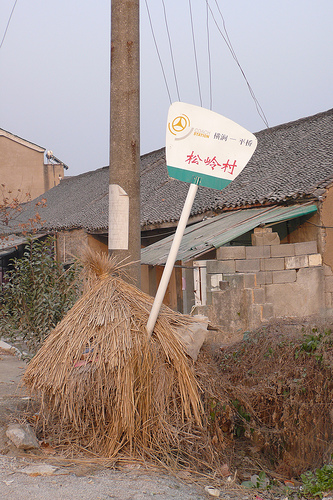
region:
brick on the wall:
[232, 257, 255, 271]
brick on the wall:
[270, 244, 294, 257]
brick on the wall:
[274, 272, 289, 282]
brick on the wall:
[246, 274, 257, 286]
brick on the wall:
[259, 305, 270, 317]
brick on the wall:
[243, 248, 264, 257]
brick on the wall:
[238, 273, 255, 284]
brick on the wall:
[250, 232, 272, 248]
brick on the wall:
[246, 247, 276, 259]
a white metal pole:
[142, 187, 200, 345]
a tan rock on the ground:
[2, 420, 37, 453]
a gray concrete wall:
[216, 227, 324, 279]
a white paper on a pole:
[107, 182, 133, 256]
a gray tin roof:
[44, 177, 90, 224]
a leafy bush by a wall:
[15, 229, 73, 341]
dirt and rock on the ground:
[6, 470, 260, 493]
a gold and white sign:
[163, 102, 257, 171]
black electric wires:
[143, 14, 240, 76]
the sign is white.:
[159, 95, 258, 195]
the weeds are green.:
[298, 460, 331, 497]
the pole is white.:
[140, 179, 204, 340]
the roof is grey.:
[0, 108, 331, 241]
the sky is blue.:
[0, 0, 331, 141]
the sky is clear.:
[0, 0, 330, 120]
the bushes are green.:
[3, 234, 86, 341]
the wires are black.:
[139, 0, 278, 138]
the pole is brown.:
[102, 1, 146, 280]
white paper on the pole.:
[99, 180, 131, 257]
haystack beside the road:
[29, 244, 206, 464]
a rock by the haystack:
[7, 421, 40, 447]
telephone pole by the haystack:
[110, 0, 141, 284]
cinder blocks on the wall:
[194, 226, 326, 347]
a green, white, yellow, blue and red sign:
[165, 100, 256, 190]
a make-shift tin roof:
[135, 200, 322, 264]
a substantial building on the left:
[0, 125, 65, 210]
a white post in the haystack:
[145, 182, 199, 337]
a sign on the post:
[108, 185, 128, 250]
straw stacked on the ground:
[17, 255, 212, 443]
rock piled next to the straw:
[4, 416, 48, 451]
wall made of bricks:
[213, 238, 326, 325]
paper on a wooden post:
[104, 180, 134, 253]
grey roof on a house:
[5, 106, 332, 221]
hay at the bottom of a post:
[20, 246, 207, 451]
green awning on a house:
[138, 203, 314, 269]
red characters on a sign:
[182, 149, 240, 175]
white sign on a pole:
[160, 99, 263, 195]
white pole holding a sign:
[142, 180, 200, 352]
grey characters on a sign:
[212, 129, 254, 152]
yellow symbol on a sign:
[167, 111, 189, 136]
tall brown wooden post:
[107, 0, 145, 295]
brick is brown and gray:
[246, 247, 270, 258]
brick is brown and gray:
[269, 242, 294, 256]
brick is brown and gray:
[295, 242, 318, 257]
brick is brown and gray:
[233, 258, 260, 272]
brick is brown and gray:
[261, 257, 284, 271]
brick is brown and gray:
[286, 254, 307, 268]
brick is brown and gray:
[307, 253, 322, 265]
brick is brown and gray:
[273, 270, 296, 284]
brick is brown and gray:
[255, 270, 271, 282]